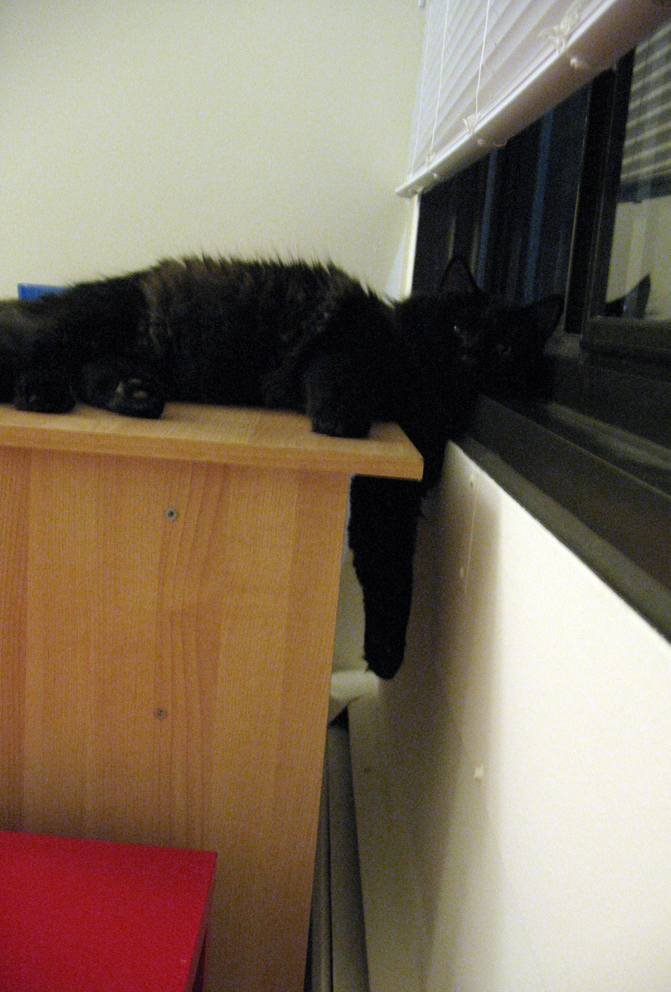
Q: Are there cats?
A: Yes, there is a cat.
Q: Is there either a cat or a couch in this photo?
A: Yes, there is a cat.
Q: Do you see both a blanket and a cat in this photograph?
A: No, there is a cat but no blankets.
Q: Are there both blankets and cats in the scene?
A: No, there is a cat but no blankets.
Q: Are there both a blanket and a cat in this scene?
A: No, there is a cat but no blankets.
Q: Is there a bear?
A: No, there are no bears.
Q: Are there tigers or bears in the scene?
A: No, there are no bears or tigers.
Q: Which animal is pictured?
A: The animal is a cat.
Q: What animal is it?
A: The animal is a cat.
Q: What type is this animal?
A: This is a cat.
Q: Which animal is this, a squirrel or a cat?
A: This is a cat.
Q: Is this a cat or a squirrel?
A: This is a cat.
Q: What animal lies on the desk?
A: The cat lies on the desk.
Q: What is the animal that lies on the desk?
A: The animal is a cat.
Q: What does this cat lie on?
A: The cat lies on the desk.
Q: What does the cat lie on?
A: The cat lies on the desk.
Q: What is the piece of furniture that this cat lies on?
A: The piece of furniture is a desk.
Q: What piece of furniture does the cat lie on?
A: The cat lies on the desk.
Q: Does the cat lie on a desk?
A: Yes, the cat lies on a desk.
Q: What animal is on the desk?
A: The cat is on the desk.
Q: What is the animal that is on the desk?
A: The animal is a cat.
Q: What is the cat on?
A: The cat is on the desk.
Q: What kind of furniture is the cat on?
A: The cat is on the desk.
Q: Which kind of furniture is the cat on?
A: The cat is on the desk.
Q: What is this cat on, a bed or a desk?
A: The cat is on a desk.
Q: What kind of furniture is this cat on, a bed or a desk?
A: The cat is on a desk.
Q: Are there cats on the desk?
A: Yes, there is a cat on the desk.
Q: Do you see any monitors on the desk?
A: No, there is a cat on the desk.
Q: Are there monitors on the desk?
A: No, there is a cat on the desk.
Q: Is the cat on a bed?
A: No, the cat is on the desk.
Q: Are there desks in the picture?
A: Yes, there is a desk.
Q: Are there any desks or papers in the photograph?
A: Yes, there is a desk.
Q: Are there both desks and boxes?
A: No, there is a desk but no boxes.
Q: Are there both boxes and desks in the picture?
A: No, there is a desk but no boxes.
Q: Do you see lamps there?
A: No, there are no lamps.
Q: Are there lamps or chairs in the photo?
A: No, there are no lamps or chairs.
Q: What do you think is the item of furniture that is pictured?
A: The piece of furniture is a desk.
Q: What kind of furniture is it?
A: The piece of furniture is a desk.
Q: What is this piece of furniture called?
A: This is a desk.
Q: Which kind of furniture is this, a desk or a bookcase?
A: This is a desk.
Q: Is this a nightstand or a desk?
A: This is a desk.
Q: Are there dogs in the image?
A: No, there are no dogs.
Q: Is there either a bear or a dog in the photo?
A: No, there are no dogs or bears.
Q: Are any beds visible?
A: No, there are no beds.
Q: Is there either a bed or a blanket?
A: No, there are no beds or blankets.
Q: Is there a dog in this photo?
A: No, there are no dogs.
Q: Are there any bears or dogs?
A: No, there are no dogs or bears.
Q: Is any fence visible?
A: No, there are no fences.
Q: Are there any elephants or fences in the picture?
A: No, there are no fences or elephants.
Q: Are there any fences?
A: No, there are no fences.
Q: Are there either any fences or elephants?
A: No, there are no fences or elephants.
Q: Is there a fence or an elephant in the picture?
A: No, there are no fences or elephants.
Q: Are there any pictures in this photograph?
A: No, there are no pictures.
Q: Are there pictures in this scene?
A: No, there are no pictures.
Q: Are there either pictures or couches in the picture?
A: No, there are no pictures or couches.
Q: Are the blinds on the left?
A: No, the blinds are on the right of the image.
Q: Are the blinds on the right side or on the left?
A: The blinds are on the right of the image.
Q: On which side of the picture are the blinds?
A: The blinds are on the right of the image.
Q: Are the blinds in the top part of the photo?
A: Yes, the blinds are in the top of the image.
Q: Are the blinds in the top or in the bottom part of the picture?
A: The blinds are in the top of the image.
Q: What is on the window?
A: The blinds are on the window.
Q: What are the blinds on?
A: The blinds are on the window.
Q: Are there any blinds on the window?
A: Yes, there are blinds on the window.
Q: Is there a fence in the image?
A: No, there are no fences.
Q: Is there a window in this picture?
A: Yes, there is a window.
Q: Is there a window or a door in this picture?
A: Yes, there is a window.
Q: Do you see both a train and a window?
A: No, there is a window but no trains.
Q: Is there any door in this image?
A: No, there are no doors.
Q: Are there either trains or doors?
A: No, there are no doors or trains.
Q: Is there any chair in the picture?
A: No, there are no chairs.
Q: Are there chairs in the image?
A: No, there are no chairs.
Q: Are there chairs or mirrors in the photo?
A: No, there are no chairs or mirrors.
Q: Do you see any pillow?
A: No, there are no pillows.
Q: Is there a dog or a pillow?
A: No, there are no pillows or dogs.